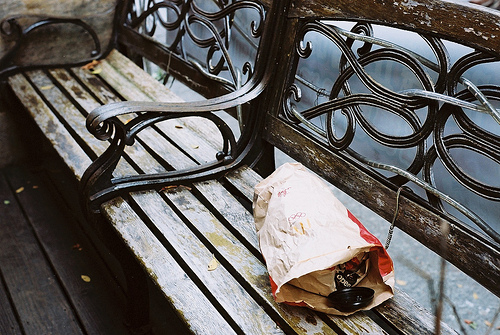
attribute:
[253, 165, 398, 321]
bag — open, papery, red, tan, brown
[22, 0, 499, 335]
bench — wooden, painted, iron, wood, metal, big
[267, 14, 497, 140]
bench back — metal, ornate, curvy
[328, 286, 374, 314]
lid — black, plastic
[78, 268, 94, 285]
leaf — yellow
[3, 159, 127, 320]
ground — wooden, dark brown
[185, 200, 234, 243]
paint — chipped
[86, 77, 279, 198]
arm rest — metal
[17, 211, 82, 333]
boards — wooden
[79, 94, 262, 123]
bench handle — iron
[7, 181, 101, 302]
leaves — small, golden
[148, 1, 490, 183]
stone wall — tall, gray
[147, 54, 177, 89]
small lights — plastic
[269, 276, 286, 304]
trim — red